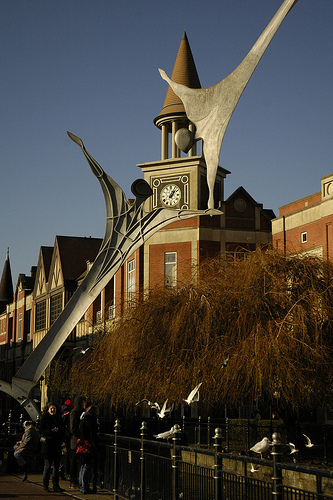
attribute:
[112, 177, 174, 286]
statues — long, gray, metal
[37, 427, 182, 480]
people — looking, watchng, standing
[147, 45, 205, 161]
tower — above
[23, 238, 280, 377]
buildings — area, large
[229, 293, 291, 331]
tree — big, brown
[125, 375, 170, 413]
birds — white, flying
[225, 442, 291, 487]
fence — black, metal, iron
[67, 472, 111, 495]
jeans — blue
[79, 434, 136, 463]
gate — iron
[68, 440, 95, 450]
bag — black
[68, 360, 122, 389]
bush — green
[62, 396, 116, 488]
woman — walking, sitting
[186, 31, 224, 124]
cone — brown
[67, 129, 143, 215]
sculpture — metal, art